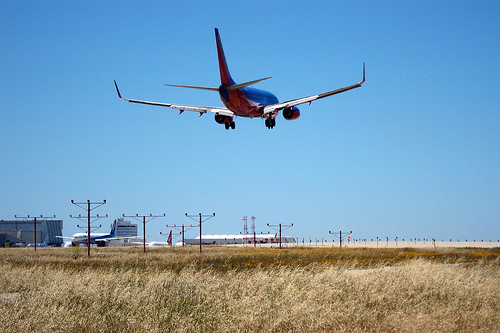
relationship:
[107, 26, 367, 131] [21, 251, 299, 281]
plane coming landing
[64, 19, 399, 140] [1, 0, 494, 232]
plane in blue sky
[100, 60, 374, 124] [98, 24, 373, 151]
wing of plane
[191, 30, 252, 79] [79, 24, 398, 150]
tail of plane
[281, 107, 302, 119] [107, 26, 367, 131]
jet engine under plane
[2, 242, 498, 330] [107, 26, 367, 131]
grass below plane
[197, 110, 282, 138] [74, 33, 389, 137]
landing gear below plane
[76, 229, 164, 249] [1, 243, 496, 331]
plane on ground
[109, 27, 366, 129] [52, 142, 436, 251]
airplane in background